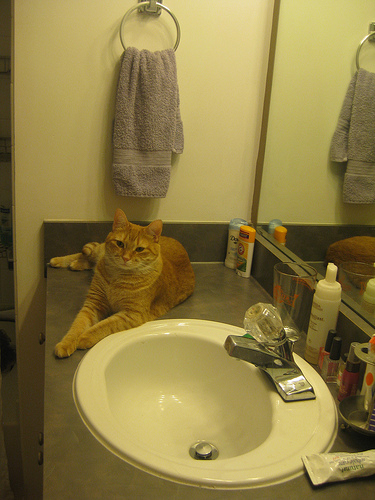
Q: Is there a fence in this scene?
A: No, there are no fences.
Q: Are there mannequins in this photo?
A: No, there are no mannequins.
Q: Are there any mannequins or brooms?
A: No, there are no mannequins or brooms.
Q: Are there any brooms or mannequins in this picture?
A: No, there are no mannequins or brooms.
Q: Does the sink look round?
A: Yes, the sink is round.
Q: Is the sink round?
A: Yes, the sink is round.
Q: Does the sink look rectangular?
A: No, the sink is round.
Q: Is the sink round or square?
A: The sink is round.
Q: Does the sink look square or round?
A: The sink is round.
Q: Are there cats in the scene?
A: Yes, there is a cat.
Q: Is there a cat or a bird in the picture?
A: Yes, there is a cat.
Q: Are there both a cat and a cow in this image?
A: No, there is a cat but no cows.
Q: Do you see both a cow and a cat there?
A: No, there is a cat but no cows.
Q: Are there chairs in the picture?
A: No, there are no chairs.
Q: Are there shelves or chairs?
A: No, there are no chairs or shelves.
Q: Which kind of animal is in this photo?
A: The animal is a cat.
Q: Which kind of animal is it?
A: The animal is a cat.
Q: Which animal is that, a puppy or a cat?
A: That is a cat.